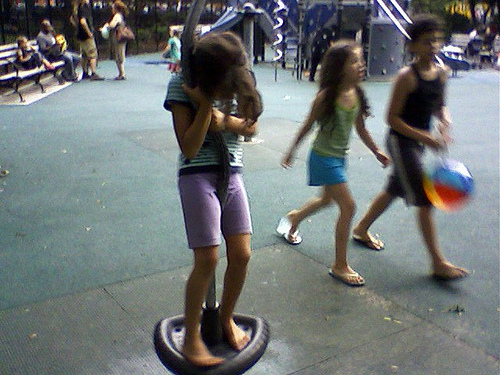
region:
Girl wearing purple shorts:
[152, 168, 229, 219]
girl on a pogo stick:
[163, 223, 268, 365]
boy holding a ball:
[401, 144, 471, 216]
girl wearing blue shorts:
[298, 135, 360, 195]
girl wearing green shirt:
[316, 95, 366, 171]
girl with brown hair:
[313, 40, 356, 72]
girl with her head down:
[188, 50, 255, 115]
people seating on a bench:
[31, 7, 73, 87]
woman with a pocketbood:
[94, 12, 162, 62]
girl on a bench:
[15, 28, 52, 78]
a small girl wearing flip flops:
[278, 24, 393, 301]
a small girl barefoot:
[147, 14, 268, 363]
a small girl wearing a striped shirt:
[132, 30, 248, 242]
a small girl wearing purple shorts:
[139, 42, 279, 253]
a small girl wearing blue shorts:
[300, 16, 373, 235]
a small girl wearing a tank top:
[287, 18, 402, 233]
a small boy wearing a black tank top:
[371, 9, 456, 151]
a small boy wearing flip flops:
[369, 18, 482, 298]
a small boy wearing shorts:
[377, 8, 494, 253]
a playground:
[148, 0, 483, 105]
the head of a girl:
[322, 37, 373, 93]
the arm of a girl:
[284, 89, 334, 156]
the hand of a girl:
[278, 144, 300, 173]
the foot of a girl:
[329, 257, 365, 285]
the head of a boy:
[397, 10, 452, 68]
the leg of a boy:
[389, 133, 443, 260]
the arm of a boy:
[383, 68, 426, 141]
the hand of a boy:
[420, 130, 446, 150]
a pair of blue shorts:
[303, 147, 349, 192]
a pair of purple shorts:
[176, 165, 258, 253]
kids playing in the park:
[84, 0, 455, 356]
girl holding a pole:
[146, 1, 268, 293]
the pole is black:
[178, 7, 252, 366]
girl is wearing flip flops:
[260, 189, 362, 319]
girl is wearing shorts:
[150, 150, 267, 266]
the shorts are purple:
[174, 150, 251, 242]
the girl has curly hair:
[300, 21, 372, 141]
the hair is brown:
[294, 28, 374, 127]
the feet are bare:
[148, 284, 270, 368]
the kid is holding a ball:
[386, 0, 478, 252]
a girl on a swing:
[124, 2, 281, 372]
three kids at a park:
[160, 20, 495, 368]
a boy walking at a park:
[355, 11, 482, 301]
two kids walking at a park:
[274, 13, 475, 300]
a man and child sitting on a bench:
[1, 20, 81, 100]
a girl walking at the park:
[278, 25, 393, 297]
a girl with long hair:
[311, 33, 377, 137]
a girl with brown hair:
[316, 34, 373, 140]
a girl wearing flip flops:
[280, 27, 373, 294]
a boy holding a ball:
[377, 8, 475, 290]